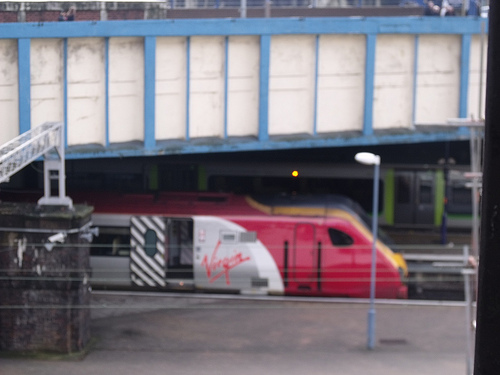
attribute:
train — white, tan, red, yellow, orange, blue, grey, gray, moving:
[0, 196, 410, 297]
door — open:
[163, 215, 196, 286]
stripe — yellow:
[243, 194, 408, 275]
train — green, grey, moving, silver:
[16, 162, 482, 231]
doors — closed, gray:
[393, 165, 435, 224]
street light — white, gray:
[352, 147, 379, 351]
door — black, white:
[127, 210, 162, 289]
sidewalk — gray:
[0, 288, 477, 374]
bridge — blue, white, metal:
[0, 0, 499, 164]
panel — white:
[68, 39, 105, 146]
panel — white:
[109, 35, 143, 147]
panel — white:
[155, 37, 186, 139]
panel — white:
[189, 35, 225, 137]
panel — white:
[267, 33, 315, 132]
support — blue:
[144, 33, 155, 147]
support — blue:
[257, 33, 269, 141]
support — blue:
[365, 35, 374, 130]